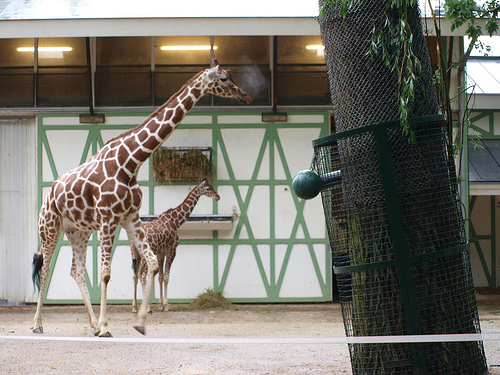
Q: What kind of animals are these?
A: Giraffes.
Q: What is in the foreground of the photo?
A: Tree.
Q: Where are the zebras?
A: The zoo.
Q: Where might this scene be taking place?
A: Zoo.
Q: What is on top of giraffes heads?
A: Horns.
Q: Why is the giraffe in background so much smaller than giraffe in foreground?
A: It is younger.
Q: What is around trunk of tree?
A: Wire cage.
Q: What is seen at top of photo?
A: Windows.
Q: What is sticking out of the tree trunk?
A: Branches.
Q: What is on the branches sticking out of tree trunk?
A: Leaves.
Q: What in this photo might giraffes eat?
A: Leaves.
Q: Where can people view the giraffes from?
A: Windows.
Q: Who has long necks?
A: The giraffe.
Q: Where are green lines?
A: On the wall.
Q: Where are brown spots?
A: On giraffe.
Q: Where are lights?
A: On a ceiling.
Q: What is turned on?
A: The lights.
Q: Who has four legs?
A: One giraffe.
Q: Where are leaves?
A: On a tree.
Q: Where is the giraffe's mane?
A: On giraffe's neck.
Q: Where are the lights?
A: Inside a building.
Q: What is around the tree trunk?
A: Green cage.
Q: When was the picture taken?
A: During the day.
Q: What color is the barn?
A: White.